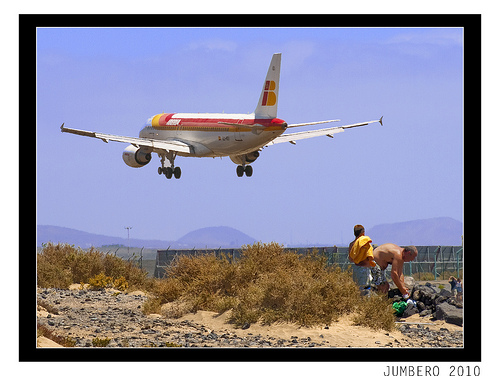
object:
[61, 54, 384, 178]
airplane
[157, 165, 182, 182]
landing gear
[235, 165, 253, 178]
landing gear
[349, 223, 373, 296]
man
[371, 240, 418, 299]
man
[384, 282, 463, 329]
rocks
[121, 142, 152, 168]
engine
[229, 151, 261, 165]
engine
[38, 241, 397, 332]
foliage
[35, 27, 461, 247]
sky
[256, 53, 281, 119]
tail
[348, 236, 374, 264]
shirt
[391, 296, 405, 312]
cloth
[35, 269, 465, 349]
beach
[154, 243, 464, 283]
fence